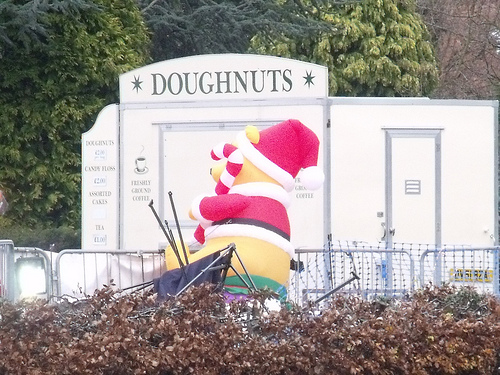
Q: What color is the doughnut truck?
A: Its white.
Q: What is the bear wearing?
A: A red stocking cap.